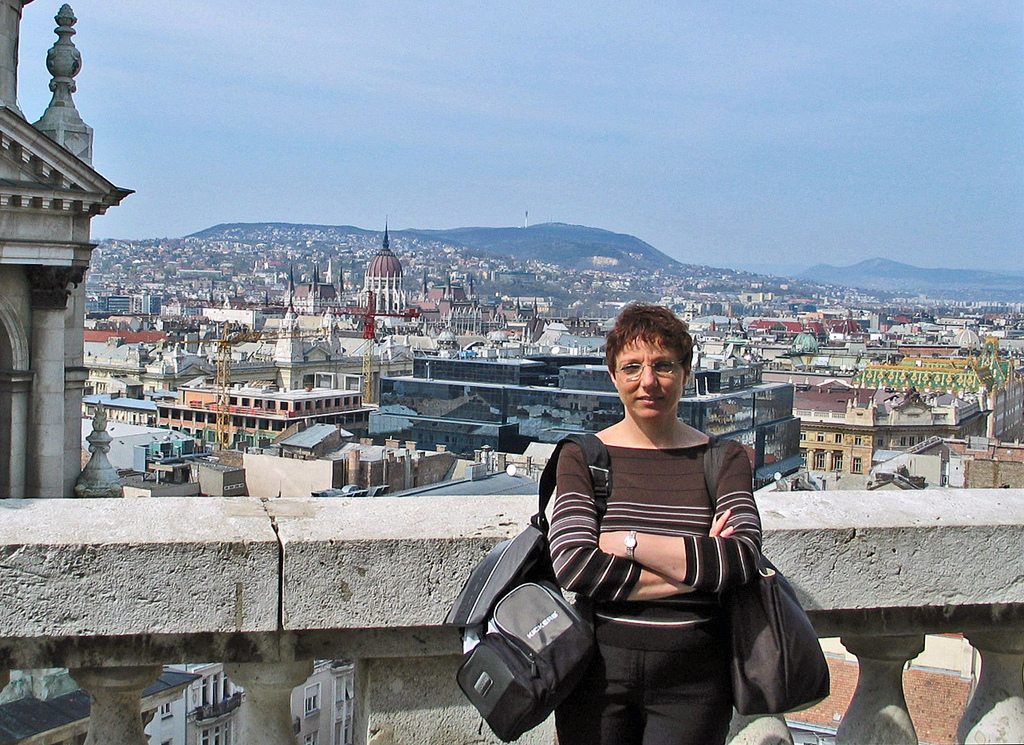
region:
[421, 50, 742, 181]
blue and white sky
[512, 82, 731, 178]
white clouds in sky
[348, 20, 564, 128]
faint clouds in sky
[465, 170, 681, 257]
tall trees in distance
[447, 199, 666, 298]
mountain is in background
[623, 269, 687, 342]
woman has brown hair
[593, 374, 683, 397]
woman is wearing glasses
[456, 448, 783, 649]
brown and grey shirt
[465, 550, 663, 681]
black and grey basket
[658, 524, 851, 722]
woman has black bag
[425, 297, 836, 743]
Woman in the forefront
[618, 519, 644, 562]
Watch on the wrist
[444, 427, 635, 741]
Gray and black bag on the shoulder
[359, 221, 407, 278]
dome on the building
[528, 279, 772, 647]
Striped shirt on the woman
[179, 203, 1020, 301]
Mountains in the distance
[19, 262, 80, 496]
Column on the building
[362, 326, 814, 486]
Building in the distance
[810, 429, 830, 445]
Window in the building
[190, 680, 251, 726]
Balcony on the building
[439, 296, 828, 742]
The woman is carrying two bags.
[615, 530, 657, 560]
A watch is on the woman's wrist.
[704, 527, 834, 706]
The bag the woman is carrying is black.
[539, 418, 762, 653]
The woman is wearing a striped sweater.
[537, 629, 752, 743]
The woman is wearing a pair of black pants.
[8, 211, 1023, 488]
The city is large.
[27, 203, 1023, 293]
The mountains are by the city.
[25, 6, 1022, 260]
The sky is blue.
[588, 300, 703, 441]
Head of a woman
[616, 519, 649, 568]
Watch on a woman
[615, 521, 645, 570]
Silver watch on a woman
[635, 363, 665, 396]
Nose of a woman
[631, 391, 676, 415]
Mouth of a woman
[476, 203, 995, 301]
Mountains in the distance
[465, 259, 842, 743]
woman posing for a picture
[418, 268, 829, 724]
woman carrying several bags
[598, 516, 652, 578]
a small silver watch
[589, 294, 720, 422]
a woman wearing glasses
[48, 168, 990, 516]
a city view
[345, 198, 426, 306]
a spire on a tower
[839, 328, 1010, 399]
a building with a green and yellow roof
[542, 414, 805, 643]
a brown, black, and white striped shirt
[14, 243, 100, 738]
a stone column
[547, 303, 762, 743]
a woman with short brown hair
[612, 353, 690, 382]
eyeglasses on the woman's face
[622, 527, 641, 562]
the watch on the woman's wrist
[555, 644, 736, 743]
black pants the woman is wearing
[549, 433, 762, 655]
striped brown sweater the woman is wearing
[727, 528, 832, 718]
the black purse the woman is holding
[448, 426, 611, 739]
large black anc gray bag on the woman's shoulder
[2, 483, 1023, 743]
stone railing behind the woman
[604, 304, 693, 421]
the woman's head facing the camera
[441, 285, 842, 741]
woman posing for a picture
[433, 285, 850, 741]
woman holding a purse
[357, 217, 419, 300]
the dome of a building is red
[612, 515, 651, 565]
a clock on a wrist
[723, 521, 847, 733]
the bag is color black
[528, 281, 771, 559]
woman has short hair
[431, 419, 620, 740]
a bag on a shoulder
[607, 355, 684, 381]
glasses on woman's face